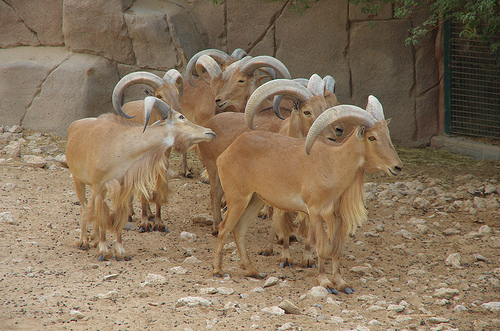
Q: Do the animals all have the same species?
A: Yes, all the animals are goats.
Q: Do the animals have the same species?
A: Yes, all the animals are goats.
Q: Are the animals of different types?
A: No, all the animals are goats.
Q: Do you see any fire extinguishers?
A: No, there are no fire extinguishers.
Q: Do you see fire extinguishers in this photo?
A: No, there are no fire extinguishers.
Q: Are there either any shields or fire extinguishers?
A: No, there are no fire extinguishers or shields.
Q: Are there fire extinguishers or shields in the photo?
A: No, there are no fire extinguishers or shields.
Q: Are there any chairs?
A: No, there are no chairs.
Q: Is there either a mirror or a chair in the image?
A: No, there are no chairs or mirrors.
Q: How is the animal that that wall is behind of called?
A: The animal is a goat.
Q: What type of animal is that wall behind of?
A: The wall is behind the goat.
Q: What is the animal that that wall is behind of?
A: The animal is a goat.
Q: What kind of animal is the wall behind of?
A: The wall is behind the goat.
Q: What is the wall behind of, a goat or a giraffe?
A: The wall is behind a goat.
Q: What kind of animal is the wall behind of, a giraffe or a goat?
A: The wall is behind a goat.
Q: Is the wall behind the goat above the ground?
A: Yes, the wall is behind the goat.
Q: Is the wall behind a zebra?
A: No, the wall is behind the goat.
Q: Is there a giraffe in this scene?
A: No, there are no giraffes.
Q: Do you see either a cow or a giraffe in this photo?
A: No, there are no giraffes or cows.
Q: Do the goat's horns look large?
A: Yes, the horns are large.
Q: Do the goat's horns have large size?
A: Yes, the horns are large.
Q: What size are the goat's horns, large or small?
A: The horns are large.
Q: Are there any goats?
A: Yes, there is a goat.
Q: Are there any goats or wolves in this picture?
A: Yes, there is a goat.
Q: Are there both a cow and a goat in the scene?
A: No, there is a goat but no cows.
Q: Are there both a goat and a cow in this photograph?
A: No, there is a goat but no cows.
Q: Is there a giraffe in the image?
A: No, there are no giraffes.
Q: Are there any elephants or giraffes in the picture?
A: No, there are no giraffes or elephants.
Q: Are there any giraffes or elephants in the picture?
A: No, there are no giraffes or elephants.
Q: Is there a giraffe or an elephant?
A: No, there are no giraffes or elephants.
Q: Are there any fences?
A: Yes, there is a fence.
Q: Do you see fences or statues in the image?
A: Yes, there is a fence.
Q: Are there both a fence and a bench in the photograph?
A: No, there is a fence but no benches.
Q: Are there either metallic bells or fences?
A: Yes, there is a metal fence.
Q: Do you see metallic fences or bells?
A: Yes, there is a metal fence.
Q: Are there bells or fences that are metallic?
A: Yes, the fence is metallic.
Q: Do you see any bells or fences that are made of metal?
A: Yes, the fence is made of metal.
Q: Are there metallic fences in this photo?
A: Yes, there is a metal fence.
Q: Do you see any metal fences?
A: Yes, there is a metal fence.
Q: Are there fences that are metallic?
A: Yes, there is a fence that is metallic.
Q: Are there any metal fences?
A: Yes, there is a fence that is made of metal.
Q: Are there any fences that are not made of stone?
A: Yes, there is a fence that is made of metal.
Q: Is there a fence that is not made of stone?
A: Yes, there is a fence that is made of metal.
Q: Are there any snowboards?
A: No, there are no snowboards.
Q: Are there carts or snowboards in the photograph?
A: No, there are no snowboards or carts.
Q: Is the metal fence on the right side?
A: Yes, the fence is on the right of the image.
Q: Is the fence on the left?
A: No, the fence is on the right of the image.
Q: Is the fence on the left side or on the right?
A: The fence is on the right of the image.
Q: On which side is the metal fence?
A: The fence is on the right of the image.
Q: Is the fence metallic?
A: Yes, the fence is metallic.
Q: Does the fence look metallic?
A: Yes, the fence is metallic.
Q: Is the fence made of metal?
A: Yes, the fence is made of metal.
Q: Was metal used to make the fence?
A: Yes, the fence is made of metal.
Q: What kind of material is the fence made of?
A: The fence is made of metal.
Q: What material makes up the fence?
A: The fence is made of metal.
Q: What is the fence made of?
A: The fence is made of metal.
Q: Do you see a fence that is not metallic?
A: No, there is a fence but it is metallic.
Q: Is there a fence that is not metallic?
A: No, there is a fence but it is metallic.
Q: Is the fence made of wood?
A: No, the fence is made of metal.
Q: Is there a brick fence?
A: No, there is a fence but it is made of metal.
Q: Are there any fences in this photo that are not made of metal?
A: No, there is a fence but it is made of metal.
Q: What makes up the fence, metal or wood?
A: The fence is made of metal.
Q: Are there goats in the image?
A: Yes, there is a goat.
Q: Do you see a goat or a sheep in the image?
A: Yes, there is a goat.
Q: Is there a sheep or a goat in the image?
A: Yes, there is a goat.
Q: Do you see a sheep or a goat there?
A: Yes, there is a goat.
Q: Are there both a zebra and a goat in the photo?
A: No, there is a goat but no zebras.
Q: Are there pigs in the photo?
A: No, there are no pigs.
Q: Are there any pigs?
A: No, there are no pigs.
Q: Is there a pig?
A: No, there are no pigs.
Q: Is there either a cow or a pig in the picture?
A: No, there are no pigs or cows.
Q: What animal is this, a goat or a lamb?
A: This is a goat.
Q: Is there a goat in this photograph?
A: Yes, there is a goat.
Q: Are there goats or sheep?
A: Yes, there is a goat.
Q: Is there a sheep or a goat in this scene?
A: Yes, there is a goat.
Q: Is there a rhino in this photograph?
A: No, there are no rhinos.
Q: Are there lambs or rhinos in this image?
A: No, there are no rhinos or lambs.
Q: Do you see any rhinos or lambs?
A: No, there are no rhinos or lambs.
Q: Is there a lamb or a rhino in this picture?
A: No, there are no rhinos or lambs.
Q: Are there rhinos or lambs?
A: No, there are no rhinos or lambs.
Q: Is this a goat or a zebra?
A: This is a goat.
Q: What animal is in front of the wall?
A: The goat is in front of the wall.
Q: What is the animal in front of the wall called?
A: The animal is a goat.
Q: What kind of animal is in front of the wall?
A: The animal is a goat.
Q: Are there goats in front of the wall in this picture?
A: Yes, there is a goat in front of the wall.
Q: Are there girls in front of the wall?
A: No, there is a goat in front of the wall.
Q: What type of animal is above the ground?
A: The animal is a goat.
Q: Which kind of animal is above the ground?
A: The animal is a goat.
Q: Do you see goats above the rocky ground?
A: Yes, there is a goat above the ground.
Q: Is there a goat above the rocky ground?
A: Yes, there is a goat above the ground.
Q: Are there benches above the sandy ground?
A: No, there is a goat above the ground.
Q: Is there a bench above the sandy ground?
A: No, there is a goat above the ground.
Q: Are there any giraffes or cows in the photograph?
A: No, there are no giraffes or cows.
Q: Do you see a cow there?
A: No, there are no cows.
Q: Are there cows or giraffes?
A: No, there are no cows or giraffes.